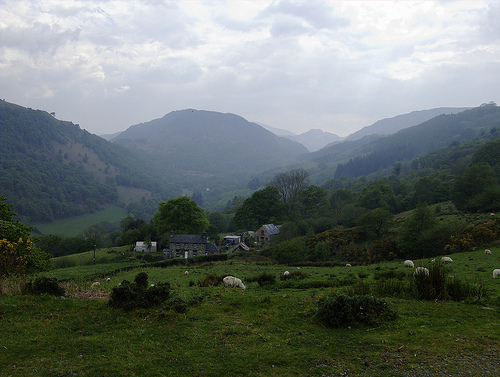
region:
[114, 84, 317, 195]
tree covered foggy mountain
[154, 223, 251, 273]
stone farm house on the hill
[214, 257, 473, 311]
herd of sheep grazing on the grass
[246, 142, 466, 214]
trees growing on the side of the mountain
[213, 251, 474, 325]
sheep grazing on the mountain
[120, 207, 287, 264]
stone house and outbuilding structures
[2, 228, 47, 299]
yellow flowers on the bush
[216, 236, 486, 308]
sheep that look like balls of white cotton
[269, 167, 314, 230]
one lonely dead tree amid the green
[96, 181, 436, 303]
idyllic countryside picture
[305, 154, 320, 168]
the cloud is hazy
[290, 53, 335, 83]
the cloud is hazy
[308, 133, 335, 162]
the cloud is hazy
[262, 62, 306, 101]
the cloud is hazy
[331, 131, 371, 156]
the cloud is hazy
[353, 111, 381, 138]
the cloud is hazy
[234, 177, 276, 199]
the cloud is hazy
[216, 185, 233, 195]
the cloud is hazy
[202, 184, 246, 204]
the cloud is hazy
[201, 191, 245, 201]
the cloud is hazy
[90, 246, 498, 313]
A herd of sheep grazing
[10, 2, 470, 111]
A sky with white clouds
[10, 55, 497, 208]
Fog over the mountains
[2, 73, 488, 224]
Mountains in the background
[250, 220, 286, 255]
An old barn with metal roof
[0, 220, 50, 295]
Yellow flowers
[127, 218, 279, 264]
An old farm house with out buildings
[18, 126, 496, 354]
A sheep farm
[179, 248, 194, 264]
A white front door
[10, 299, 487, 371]
A grass field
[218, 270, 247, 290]
a sheep eating grass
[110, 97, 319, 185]
a tall hill in the distance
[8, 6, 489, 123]
a bright cloudy blue sky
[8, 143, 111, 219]
trees on a steep hillside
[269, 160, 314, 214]
a bare leafless tree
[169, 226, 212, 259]
a large farmhouse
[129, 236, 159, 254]
a white shed behind a farmhouse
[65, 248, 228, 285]
a black wooden fence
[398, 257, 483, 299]
tall plants in a field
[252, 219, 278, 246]
a barn behind a house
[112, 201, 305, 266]
Houses in the valley of the mountains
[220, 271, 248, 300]
A sheep is grazing on grass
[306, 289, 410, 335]
Large bush in a field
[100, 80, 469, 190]
Large mountains in the background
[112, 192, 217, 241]
Trees behind the houses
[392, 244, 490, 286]
A group of sheep eating grass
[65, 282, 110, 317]
Dry grass in the middle of the field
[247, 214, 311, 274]
Large house hidden by trees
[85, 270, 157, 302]
Sheep grazing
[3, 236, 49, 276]
Dry leaves on the tree